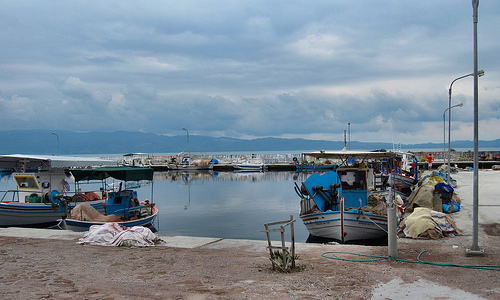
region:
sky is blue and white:
[91, 21, 321, 93]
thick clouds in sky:
[169, 34, 332, 115]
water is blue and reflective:
[173, 176, 255, 223]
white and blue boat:
[304, 179, 384, 249]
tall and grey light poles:
[416, 63, 488, 196]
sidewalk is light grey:
[456, 154, 498, 221]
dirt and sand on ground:
[34, 244, 271, 284]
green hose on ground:
[331, 244, 481, 289]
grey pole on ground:
[381, 189, 426, 262]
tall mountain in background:
[31, 126, 221, 154]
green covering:
[69, 163, 176, 193]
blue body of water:
[199, 194, 270, 233]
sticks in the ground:
[251, 208, 308, 288]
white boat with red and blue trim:
[303, 196, 383, 247]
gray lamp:
[445, 63, 490, 189]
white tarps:
[67, 222, 179, 262]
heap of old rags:
[410, 176, 470, 218]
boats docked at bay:
[5, 155, 166, 257]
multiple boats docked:
[10, 125, 430, 260]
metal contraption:
[308, 176, 343, 212]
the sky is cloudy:
[48, 72, 375, 129]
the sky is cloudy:
[30, 56, 493, 166]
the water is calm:
[167, 173, 271, 232]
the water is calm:
[161, 168, 312, 262]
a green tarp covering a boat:
[60, 159, 170, 191]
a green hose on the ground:
[304, 245, 491, 267]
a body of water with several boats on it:
[96, 158, 311, 235]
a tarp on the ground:
[70, 216, 160, 251]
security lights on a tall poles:
[430, 56, 482, 176]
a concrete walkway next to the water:
[165, 222, 255, 265]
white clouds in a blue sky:
[209, 60, 426, 105]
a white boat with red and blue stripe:
[10, 196, 45, 230]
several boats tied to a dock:
[334, 131, 430, 268]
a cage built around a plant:
[260, 203, 302, 283]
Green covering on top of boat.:
[73, 159, 158, 191]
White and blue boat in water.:
[93, 178, 175, 235]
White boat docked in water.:
[312, 183, 380, 246]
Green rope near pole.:
[398, 239, 498, 288]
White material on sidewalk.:
[87, 217, 154, 240]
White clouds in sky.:
[78, 94, 165, 122]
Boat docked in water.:
[239, 153, 260, 180]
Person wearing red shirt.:
[423, 151, 434, 166]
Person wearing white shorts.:
[421, 158, 437, 168]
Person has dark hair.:
[422, 148, 440, 163]